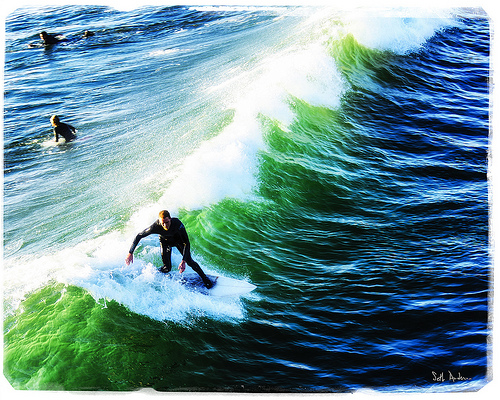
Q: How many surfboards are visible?
A: Two.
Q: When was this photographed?
A: Daytime.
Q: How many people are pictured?
A: Three.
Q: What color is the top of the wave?
A: White.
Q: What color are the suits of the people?
A: Black.